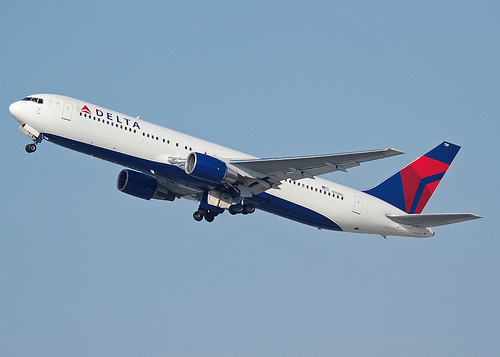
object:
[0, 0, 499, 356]
sky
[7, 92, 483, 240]
plane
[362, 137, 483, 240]
tail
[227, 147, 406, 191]
wing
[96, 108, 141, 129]
word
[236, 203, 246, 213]
back wheels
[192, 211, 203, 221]
back wheels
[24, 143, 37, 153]
front wheels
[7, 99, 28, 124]
nose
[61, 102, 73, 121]
door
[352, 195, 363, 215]
door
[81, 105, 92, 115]
graphic logo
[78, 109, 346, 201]
row of windows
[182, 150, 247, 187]
engine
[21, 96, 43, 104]
windshield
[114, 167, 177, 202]
engine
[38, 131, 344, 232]
underbelly